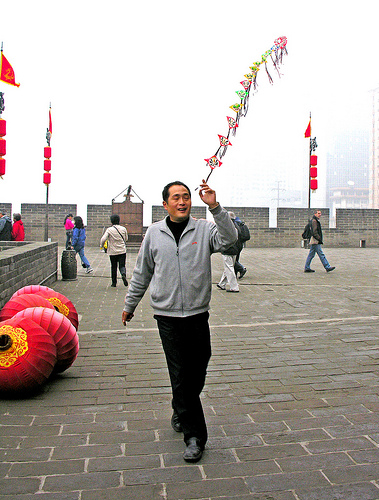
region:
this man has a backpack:
[282, 198, 342, 278]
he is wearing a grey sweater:
[118, 165, 256, 468]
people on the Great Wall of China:
[0, 175, 371, 461]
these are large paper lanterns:
[2, 279, 85, 397]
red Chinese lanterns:
[2, 274, 87, 395]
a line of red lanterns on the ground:
[1, 269, 106, 421]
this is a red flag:
[299, 110, 319, 138]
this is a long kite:
[190, 19, 288, 200]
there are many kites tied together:
[189, 29, 301, 191]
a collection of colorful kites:
[206, 27, 292, 186]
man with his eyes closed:
[114, 161, 258, 478]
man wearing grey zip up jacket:
[99, 178, 256, 479]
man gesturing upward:
[109, 161, 267, 473]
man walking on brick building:
[88, 146, 286, 482]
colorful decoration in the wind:
[189, 26, 298, 187]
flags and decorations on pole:
[291, 105, 333, 217]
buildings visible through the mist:
[261, 85, 377, 222]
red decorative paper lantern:
[4, 272, 96, 405]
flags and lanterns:
[39, 95, 59, 204]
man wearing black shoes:
[85, 158, 244, 474]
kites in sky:
[215, 45, 266, 166]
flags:
[20, 104, 64, 190]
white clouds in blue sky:
[107, 53, 129, 88]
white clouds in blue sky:
[242, 157, 258, 173]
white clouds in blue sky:
[342, 136, 369, 157]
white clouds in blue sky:
[258, 131, 308, 168]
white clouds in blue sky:
[303, 47, 338, 77]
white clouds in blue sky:
[76, 118, 98, 142]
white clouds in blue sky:
[140, 38, 164, 70]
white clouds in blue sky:
[58, 25, 114, 73]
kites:
[201, 32, 274, 164]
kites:
[276, 113, 323, 192]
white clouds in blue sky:
[87, 61, 125, 82]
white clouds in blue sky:
[108, 31, 130, 56]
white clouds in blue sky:
[112, 105, 143, 149]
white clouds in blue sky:
[163, 87, 198, 112]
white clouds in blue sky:
[88, 55, 117, 96]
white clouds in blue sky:
[75, 92, 128, 152]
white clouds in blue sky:
[138, 52, 174, 100]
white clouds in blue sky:
[92, 85, 146, 156]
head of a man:
[148, 169, 205, 234]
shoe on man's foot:
[168, 422, 214, 472]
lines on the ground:
[32, 400, 147, 490]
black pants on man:
[158, 327, 226, 410]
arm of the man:
[199, 180, 245, 249]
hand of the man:
[187, 172, 234, 219]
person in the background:
[283, 194, 333, 281]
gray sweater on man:
[115, 207, 219, 312]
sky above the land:
[68, 121, 154, 185]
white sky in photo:
[86, 106, 179, 169]